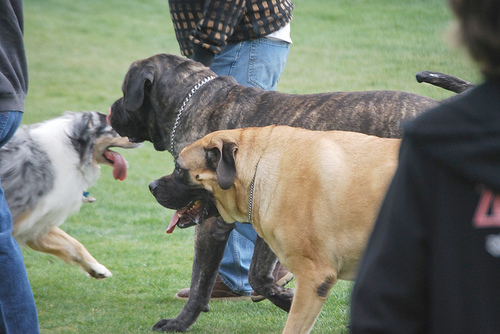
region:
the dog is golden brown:
[129, 119, 396, 304]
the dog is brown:
[108, 45, 350, 144]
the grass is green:
[111, 240, 170, 330]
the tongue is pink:
[146, 193, 219, 245]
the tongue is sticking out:
[86, 115, 152, 204]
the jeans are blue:
[2, 113, 54, 331]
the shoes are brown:
[133, 257, 330, 303]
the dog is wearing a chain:
[185, 130, 295, 241]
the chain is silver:
[151, 48, 208, 143]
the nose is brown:
[148, 169, 209, 219]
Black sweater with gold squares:
[162, 0, 300, 57]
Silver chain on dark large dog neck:
[161, 57, 220, 163]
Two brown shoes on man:
[173, 265, 300, 305]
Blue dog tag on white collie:
[75, 175, 100, 209]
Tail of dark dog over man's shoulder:
[407, 55, 477, 105]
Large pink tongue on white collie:
[102, 147, 135, 187]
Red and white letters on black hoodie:
[470, 177, 498, 265]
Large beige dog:
[144, 124, 406, 332]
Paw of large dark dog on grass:
[136, 296, 205, 331]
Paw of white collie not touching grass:
[83, 239, 115, 291]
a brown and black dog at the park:
[148, 122, 408, 328]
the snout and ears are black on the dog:
[150, 129, 242, 234]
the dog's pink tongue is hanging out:
[144, 150, 224, 235]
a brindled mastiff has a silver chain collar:
[109, 51, 456, 329]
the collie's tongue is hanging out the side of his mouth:
[6, 111, 145, 287]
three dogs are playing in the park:
[2, 52, 449, 330]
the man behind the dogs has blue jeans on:
[203, 31, 289, 283]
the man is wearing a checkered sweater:
[173, 2, 293, 61]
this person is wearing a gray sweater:
[1, 3, 35, 113]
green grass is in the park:
[3, 6, 495, 331]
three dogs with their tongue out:
[22, 21, 493, 323]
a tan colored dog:
[133, 95, 479, 325]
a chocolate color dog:
[89, 4, 460, 166]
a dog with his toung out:
[129, 109, 490, 320]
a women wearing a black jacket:
[339, 6, 496, 331]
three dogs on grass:
[10, 16, 497, 331]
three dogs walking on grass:
[7, 0, 472, 292]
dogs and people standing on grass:
[7, 0, 485, 330]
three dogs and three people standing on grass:
[0, 16, 445, 328]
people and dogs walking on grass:
[8, 3, 492, 319]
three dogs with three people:
[47, 43, 417, 278]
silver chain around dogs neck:
[160, 64, 224, 152]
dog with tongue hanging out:
[95, 137, 132, 202]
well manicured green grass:
[38, 13, 111, 79]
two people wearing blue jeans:
[12, 37, 287, 314]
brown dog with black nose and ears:
[152, 128, 287, 265]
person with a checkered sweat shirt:
[179, 0, 300, 57]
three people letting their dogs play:
[7, 31, 470, 311]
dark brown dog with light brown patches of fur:
[142, 93, 432, 128]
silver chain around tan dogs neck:
[232, 132, 274, 230]